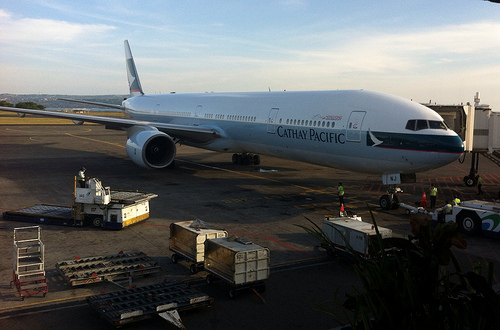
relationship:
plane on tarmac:
[42, 35, 466, 205] [30, 128, 224, 193]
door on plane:
[343, 105, 367, 150] [42, 35, 466, 205]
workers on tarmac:
[329, 184, 465, 212] [30, 128, 224, 193]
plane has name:
[42, 35, 466, 205] [272, 124, 349, 147]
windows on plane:
[280, 115, 338, 128] [42, 35, 466, 205]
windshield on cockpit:
[423, 118, 450, 128] [395, 98, 456, 150]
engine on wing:
[122, 126, 183, 166] [2, 95, 217, 141]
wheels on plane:
[380, 191, 404, 214] [42, 35, 466, 205]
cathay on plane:
[276, 125, 309, 140] [42, 35, 466, 205]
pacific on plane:
[309, 127, 347, 146] [42, 35, 466, 205]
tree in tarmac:
[14, 98, 47, 123] [30, 128, 224, 193]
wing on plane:
[2, 95, 217, 141] [42, 35, 466, 205]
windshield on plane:
[423, 118, 450, 128] [42, 35, 466, 205]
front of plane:
[404, 98, 476, 161] [42, 35, 466, 205]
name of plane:
[272, 124, 349, 147] [42, 35, 466, 205]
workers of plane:
[329, 184, 465, 212] [42, 35, 466, 205]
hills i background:
[10, 90, 59, 101] [12, 46, 106, 103]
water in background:
[47, 105, 70, 111] [12, 46, 106, 103]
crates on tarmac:
[173, 220, 267, 285] [30, 128, 224, 193]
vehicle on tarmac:
[71, 185, 133, 225] [30, 128, 224, 193]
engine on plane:
[122, 126, 183, 166] [42, 35, 466, 205]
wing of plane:
[2, 95, 217, 141] [42, 35, 466, 205]